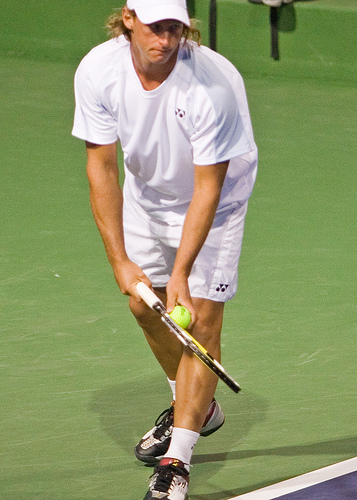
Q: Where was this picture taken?
A: Tennis game.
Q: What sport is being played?
A: Tennis.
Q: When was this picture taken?
A: Daytime.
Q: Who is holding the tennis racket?
A: Tennis player.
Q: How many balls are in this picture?
A: 1.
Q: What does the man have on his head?
A: Hat.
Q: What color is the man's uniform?
A: White.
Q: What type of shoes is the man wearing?
A: Sneakers.